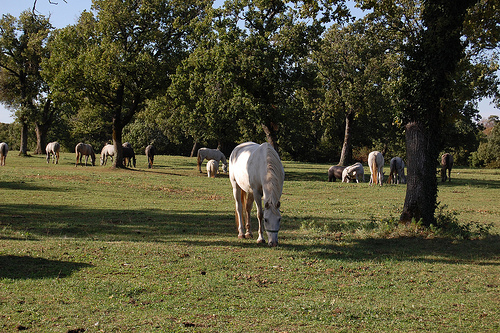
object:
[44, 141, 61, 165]
horse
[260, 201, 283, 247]
head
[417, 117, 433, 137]
ground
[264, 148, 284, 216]
mane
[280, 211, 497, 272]
shadow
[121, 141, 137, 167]
horse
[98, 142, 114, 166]
horse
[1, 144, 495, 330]
field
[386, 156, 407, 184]
horses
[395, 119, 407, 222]
right side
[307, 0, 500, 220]
tree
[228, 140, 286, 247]
horses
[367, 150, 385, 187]
horses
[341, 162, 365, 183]
horses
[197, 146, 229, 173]
horses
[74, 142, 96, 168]
horses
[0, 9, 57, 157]
tree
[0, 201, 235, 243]
shadow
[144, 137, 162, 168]
horse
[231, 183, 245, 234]
legs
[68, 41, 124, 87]
leaves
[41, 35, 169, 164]
tree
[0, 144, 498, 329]
grass